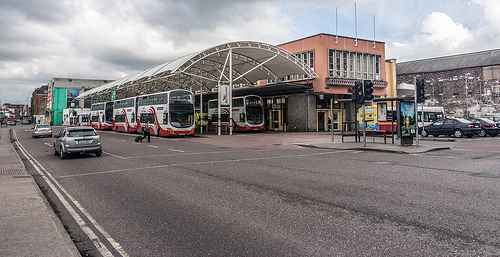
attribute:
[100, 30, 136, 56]
cloud — big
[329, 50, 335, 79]
window — tall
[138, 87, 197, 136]
bus — parked, white, double decker, red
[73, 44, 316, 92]
roof — gray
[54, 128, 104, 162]
car — silver, driving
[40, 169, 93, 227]
line — white, painted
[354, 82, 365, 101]
light — mounted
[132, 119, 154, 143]
person — walking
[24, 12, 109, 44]
cloud — large, big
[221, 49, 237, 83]
frame — silver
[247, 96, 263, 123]
window — large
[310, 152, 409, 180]
street — black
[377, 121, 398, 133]
object — red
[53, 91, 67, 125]
object — teal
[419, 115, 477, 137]
car — parked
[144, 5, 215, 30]
cloud — dark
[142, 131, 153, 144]
pants — black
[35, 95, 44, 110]
building — red